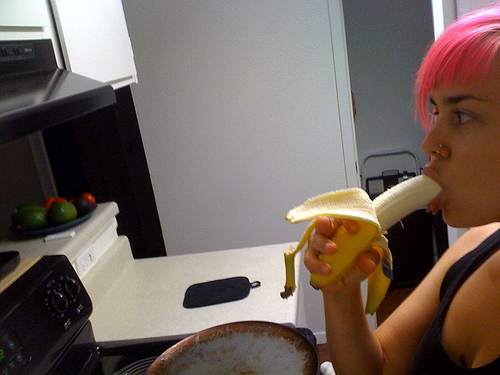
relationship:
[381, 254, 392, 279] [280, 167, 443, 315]
sticker on banana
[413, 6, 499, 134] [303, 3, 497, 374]
hair on girl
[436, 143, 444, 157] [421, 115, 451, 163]
ring in nose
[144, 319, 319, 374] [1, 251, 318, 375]
plate on oven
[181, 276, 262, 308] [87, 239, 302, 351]
potholder on counter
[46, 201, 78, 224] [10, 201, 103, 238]
lime on dish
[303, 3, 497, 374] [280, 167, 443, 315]
girl eating banana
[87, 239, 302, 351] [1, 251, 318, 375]
counter by oven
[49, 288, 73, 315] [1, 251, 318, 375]
knob on oven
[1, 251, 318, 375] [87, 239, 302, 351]
oven next to counter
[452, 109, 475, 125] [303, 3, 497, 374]
eye of girl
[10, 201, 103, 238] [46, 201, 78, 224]
dish of lime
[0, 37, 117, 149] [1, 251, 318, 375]
hood above oven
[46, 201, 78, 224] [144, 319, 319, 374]
lime on plate